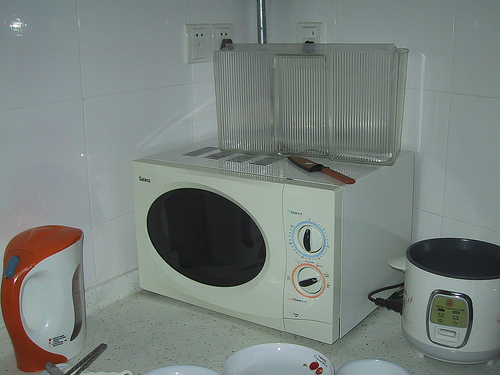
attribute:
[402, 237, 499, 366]
slow cooker — white, black, green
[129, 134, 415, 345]
microwave — white, black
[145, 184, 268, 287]
window — black, tinted, dark, oval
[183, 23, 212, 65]
electrical outlet — white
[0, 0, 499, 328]
wall — white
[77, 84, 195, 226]
tile — white, glossy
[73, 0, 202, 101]
tile — white, glossy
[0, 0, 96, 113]
tile — white, glossy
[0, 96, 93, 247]
tile — white, glossy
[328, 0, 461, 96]
tile — white, glossy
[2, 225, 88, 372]
pitcher — red, white, orange, tall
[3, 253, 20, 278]
button — blue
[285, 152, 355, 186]
knife — small, short, red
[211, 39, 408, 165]
case — large, plastic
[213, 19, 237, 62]
electrical outlet — white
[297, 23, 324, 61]
electrical outlet — white